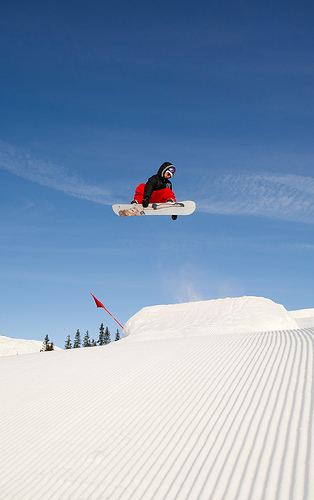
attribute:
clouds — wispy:
[32, 150, 302, 224]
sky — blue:
[5, 6, 299, 323]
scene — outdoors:
[1, 3, 311, 497]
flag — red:
[76, 283, 136, 346]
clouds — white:
[1, 130, 312, 245]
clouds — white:
[4, 123, 309, 218]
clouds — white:
[96, 243, 171, 280]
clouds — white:
[1, 134, 100, 213]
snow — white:
[30, 371, 244, 443]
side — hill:
[1, 322, 313, 496]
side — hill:
[1, 295, 310, 497]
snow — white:
[66, 392, 301, 498]